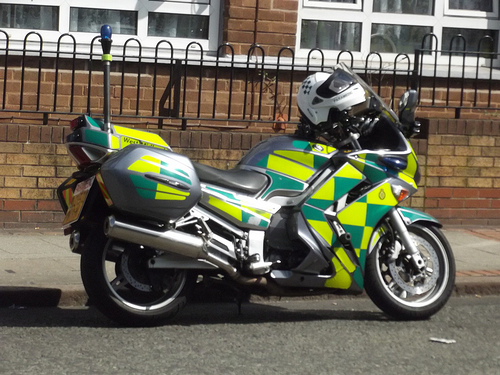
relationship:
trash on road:
[404, 322, 457, 363] [2, 293, 494, 373]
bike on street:
[74, 68, 460, 338] [2, 299, 494, 373]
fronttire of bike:
[368, 204, 457, 322] [53, 60, 456, 323]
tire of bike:
[75, 236, 123, 314] [53, 60, 456, 323]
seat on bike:
[190, 158, 268, 193] [53, 60, 456, 323]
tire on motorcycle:
[79, 215, 196, 326] [64, 69, 451, 333]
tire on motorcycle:
[364, 217, 456, 318] [64, 69, 451, 333]